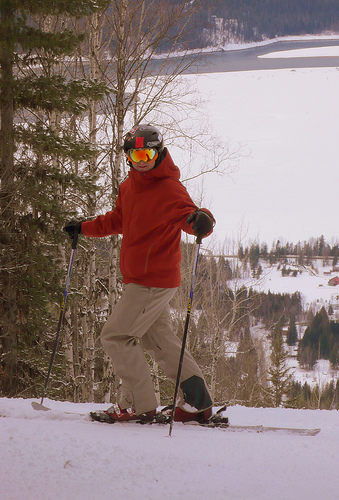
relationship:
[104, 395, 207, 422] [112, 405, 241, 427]
ski boots attached to skis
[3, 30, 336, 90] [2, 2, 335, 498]
river in landscape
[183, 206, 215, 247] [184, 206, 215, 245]
glove on hand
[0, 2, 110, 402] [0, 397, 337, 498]
evergreen tree on hill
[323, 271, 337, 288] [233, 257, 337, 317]
house in valley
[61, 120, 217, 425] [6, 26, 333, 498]
man in mountains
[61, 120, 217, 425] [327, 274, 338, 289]
man close to house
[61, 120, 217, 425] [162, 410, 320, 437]
man using snow ski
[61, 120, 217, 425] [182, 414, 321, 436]
man using skis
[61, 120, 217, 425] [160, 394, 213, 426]
man wearing ski boots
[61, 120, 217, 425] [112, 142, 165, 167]
man wearing warm clothing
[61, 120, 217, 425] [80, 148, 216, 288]
man wearing jacket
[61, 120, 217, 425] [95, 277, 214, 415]
man wearing pants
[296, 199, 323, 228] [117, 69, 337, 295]
part of snow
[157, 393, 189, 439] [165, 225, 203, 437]
edge of ski pole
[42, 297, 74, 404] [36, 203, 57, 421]
part of rail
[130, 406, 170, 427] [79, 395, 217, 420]
part of skate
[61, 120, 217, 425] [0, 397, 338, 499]
man on hill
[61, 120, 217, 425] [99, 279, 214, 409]
man wearing pants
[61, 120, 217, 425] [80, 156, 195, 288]
man wearing jacket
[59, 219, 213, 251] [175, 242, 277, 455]
handles of poles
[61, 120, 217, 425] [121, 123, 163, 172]
man wearing helmet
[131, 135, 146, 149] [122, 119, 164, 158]
sticker on helmet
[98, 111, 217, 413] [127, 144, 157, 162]
man wearing goggles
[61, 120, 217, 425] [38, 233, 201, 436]
man holds ski poles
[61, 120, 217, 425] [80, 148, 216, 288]
man wears jacket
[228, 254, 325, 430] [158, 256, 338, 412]
trees growing on a valley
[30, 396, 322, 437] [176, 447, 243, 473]
skis in snow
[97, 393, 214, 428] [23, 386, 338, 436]
ski boots on skis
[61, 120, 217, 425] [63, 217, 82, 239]
man wears glove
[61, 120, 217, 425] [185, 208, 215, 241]
man wears glove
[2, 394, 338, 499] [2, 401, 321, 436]
snow covering skis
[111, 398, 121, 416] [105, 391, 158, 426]
strap on ski boots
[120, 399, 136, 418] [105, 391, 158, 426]
strap on ski boots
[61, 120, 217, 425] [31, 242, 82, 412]
man holds ski pole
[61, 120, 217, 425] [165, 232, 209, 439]
man holds ski pole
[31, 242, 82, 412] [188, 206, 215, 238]
ski pole in hand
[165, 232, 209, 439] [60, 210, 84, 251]
ski pole in hand